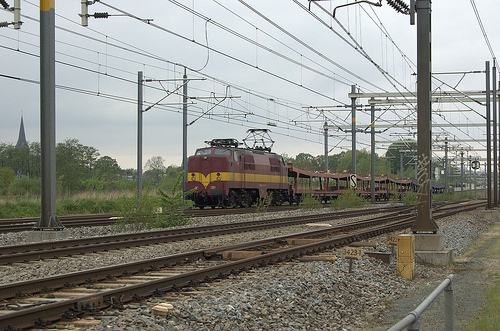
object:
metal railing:
[387, 274, 454, 331]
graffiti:
[430, 179, 434, 219]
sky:
[1, 2, 497, 175]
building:
[15, 109, 29, 147]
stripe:
[188, 172, 288, 189]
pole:
[410, 0, 439, 233]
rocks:
[273, 275, 367, 309]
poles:
[32, 0, 441, 231]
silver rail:
[390, 267, 456, 328]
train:
[183, 129, 445, 209]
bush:
[111, 170, 198, 235]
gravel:
[0, 206, 331, 247]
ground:
[100, 203, 500, 331]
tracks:
[0, 188, 499, 331]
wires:
[0, 0, 500, 151]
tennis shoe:
[187, 129, 293, 210]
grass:
[0, 137, 198, 235]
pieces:
[220, 235, 396, 273]